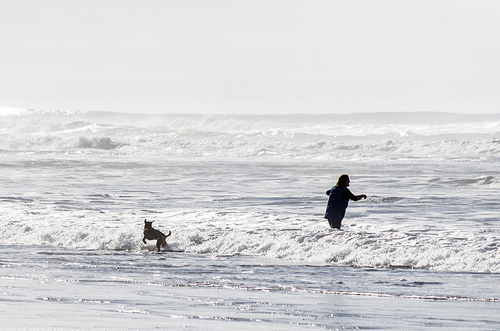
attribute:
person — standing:
[314, 163, 362, 251]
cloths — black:
[330, 194, 346, 225]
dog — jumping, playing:
[138, 211, 169, 252]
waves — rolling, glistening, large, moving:
[26, 212, 403, 266]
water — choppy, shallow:
[21, 120, 493, 269]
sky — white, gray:
[34, 11, 488, 107]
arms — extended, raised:
[345, 189, 374, 202]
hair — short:
[336, 177, 346, 188]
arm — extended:
[349, 192, 376, 203]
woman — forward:
[315, 158, 356, 245]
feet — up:
[140, 233, 152, 249]